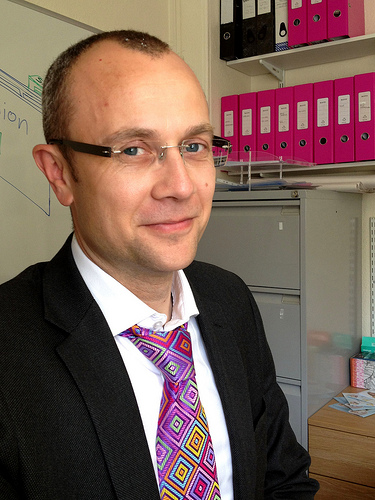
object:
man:
[0, 27, 319, 500]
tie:
[118, 324, 222, 500]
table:
[307, 387, 375, 500]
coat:
[0, 230, 318, 500]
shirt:
[70, 232, 234, 500]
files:
[216, 72, 375, 166]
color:
[219, 71, 374, 163]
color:
[216, 0, 278, 62]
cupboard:
[193, 190, 375, 452]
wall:
[26, 0, 172, 47]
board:
[0, 1, 103, 284]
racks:
[226, 152, 298, 191]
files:
[215, 177, 321, 191]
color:
[160, 365, 218, 500]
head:
[32, 30, 216, 270]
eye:
[116, 141, 150, 162]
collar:
[71, 238, 200, 340]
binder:
[221, 92, 239, 160]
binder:
[239, 90, 257, 162]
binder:
[256, 89, 276, 161]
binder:
[276, 86, 292, 165]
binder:
[293, 83, 314, 167]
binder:
[313, 79, 334, 167]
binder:
[334, 74, 356, 164]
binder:
[353, 70, 375, 162]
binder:
[287, 0, 307, 47]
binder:
[308, 1, 327, 41]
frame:
[45, 136, 232, 159]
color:
[172, 332, 193, 361]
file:
[273, 0, 291, 50]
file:
[327, 0, 364, 40]